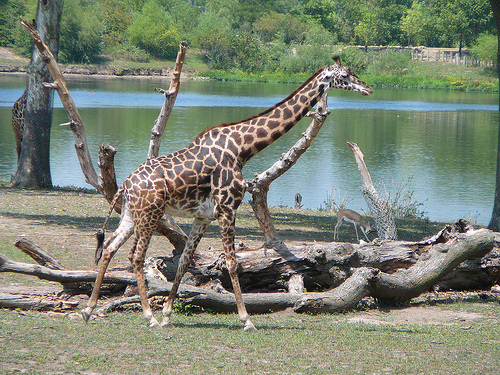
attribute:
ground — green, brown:
[3, 182, 498, 367]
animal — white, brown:
[66, 55, 381, 346]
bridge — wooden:
[359, 30, 491, 77]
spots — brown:
[178, 158, 222, 189]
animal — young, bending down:
[331, 210, 368, 248]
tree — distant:
[202, 29, 285, 86]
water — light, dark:
[0, 72, 499, 227]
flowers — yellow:
[289, 49, 434, 91]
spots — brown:
[162, 152, 232, 189]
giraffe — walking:
[76, 48, 379, 331]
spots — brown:
[166, 148, 234, 206]